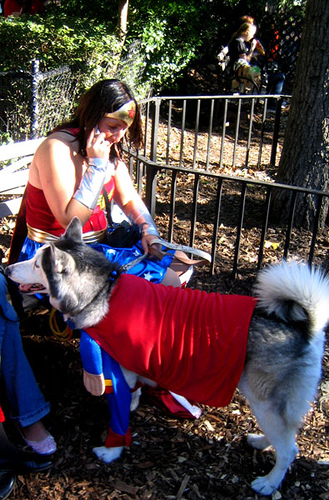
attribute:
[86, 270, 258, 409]
cape — red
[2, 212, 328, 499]
dog — black and white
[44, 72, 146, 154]
hair — brunette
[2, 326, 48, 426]
jeans — blue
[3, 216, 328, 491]
husky — black, white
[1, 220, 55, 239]
cape — cloth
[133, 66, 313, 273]
fence — wrought-iron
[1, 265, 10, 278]
nose — black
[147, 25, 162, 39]
leaves — green